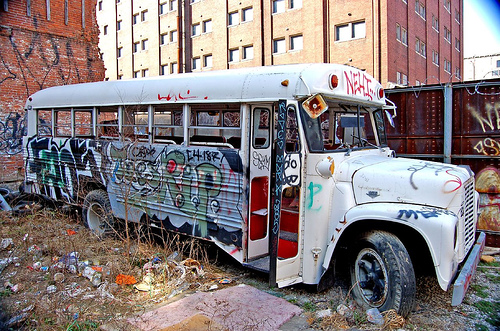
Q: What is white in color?
A: Bus.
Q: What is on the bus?
A: Wheels.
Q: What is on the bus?
A: Writing.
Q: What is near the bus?
A: Building.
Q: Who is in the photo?
A: No people.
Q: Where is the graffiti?
A: On the bus.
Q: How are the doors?
A: Open.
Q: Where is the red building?
A: In the back of the bus.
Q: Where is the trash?
A: On the ground.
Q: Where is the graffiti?
A: On the side of the bus.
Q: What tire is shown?
A: The front passenger tire.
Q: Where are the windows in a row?
A: On the bus.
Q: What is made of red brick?
A: The buildings.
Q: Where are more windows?
A: On the brick building.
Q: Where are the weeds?
A: Beside the bus.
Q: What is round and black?
A: Tires.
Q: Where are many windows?
A: On the building.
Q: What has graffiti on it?
A: The bus.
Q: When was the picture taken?
A: During daytime.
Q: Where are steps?
A: In the bus.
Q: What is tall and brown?
A: A building.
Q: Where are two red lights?
A: On front of the bus.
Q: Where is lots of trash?
A: On the ground.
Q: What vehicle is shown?
A: Bus.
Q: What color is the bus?
A: White.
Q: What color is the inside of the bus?
A: Red.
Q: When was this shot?
A: Daytime.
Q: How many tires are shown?
A: 2.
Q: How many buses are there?
A: 1.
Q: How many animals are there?
A: 0.